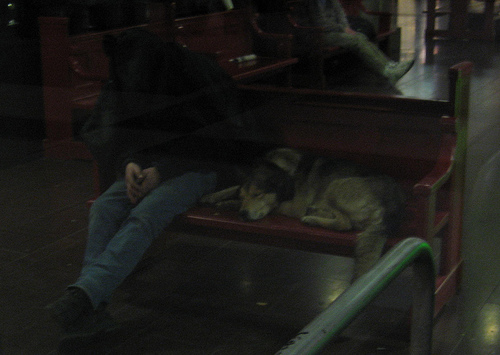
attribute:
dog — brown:
[198, 146, 405, 282]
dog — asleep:
[202, 145, 409, 229]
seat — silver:
[150, 60, 472, 320]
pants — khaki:
[317, 29, 428, 89]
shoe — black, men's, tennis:
[38, 283, 102, 337]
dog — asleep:
[186, 146, 411, 241]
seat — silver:
[82, 60, 475, 321]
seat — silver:
[116, 104, 483, 274]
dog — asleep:
[193, 143, 411, 288]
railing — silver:
[271, 239, 445, 350]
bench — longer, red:
[35, 4, 305, 161]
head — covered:
[105, 26, 189, 122]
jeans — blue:
[64, 156, 216, 315]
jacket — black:
[122, 62, 232, 177]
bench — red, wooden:
[93, 76, 475, 311]